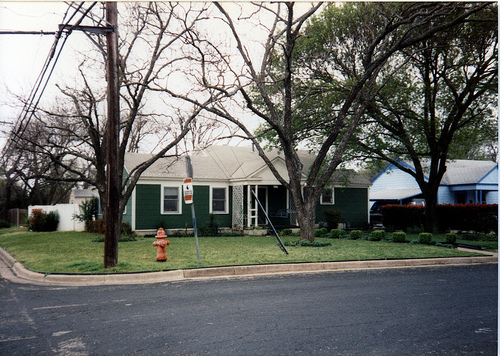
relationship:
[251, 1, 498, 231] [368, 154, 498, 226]
tree in front of house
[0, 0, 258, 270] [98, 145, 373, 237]
tree in front of house